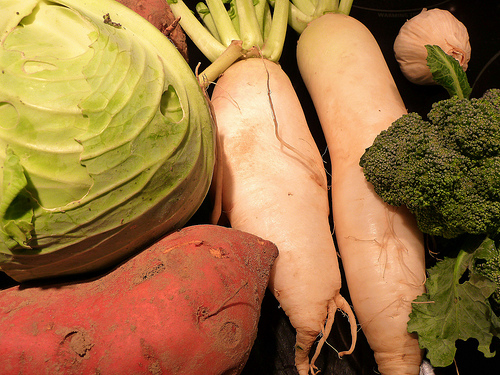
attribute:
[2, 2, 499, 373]
vegetable — freshly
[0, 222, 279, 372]
vegetable — dirt residue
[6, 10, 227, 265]
cabbage — round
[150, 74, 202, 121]
hole — one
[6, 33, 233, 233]
cabbage — green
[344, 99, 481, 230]
broccoli — dirty